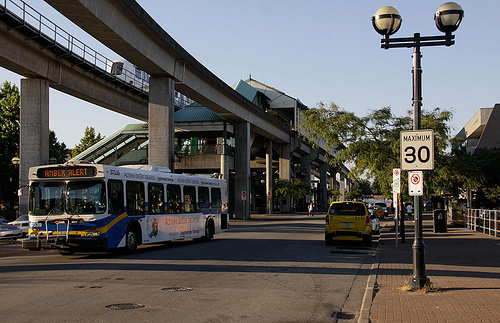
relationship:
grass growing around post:
[405, 277, 433, 297] [407, 28, 432, 293]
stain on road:
[208, 309, 230, 322] [1, 210, 372, 322]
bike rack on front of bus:
[44, 214, 70, 242] [30, 161, 231, 243]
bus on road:
[30, 161, 231, 243] [1, 210, 372, 322]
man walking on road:
[405, 200, 415, 221] [1, 210, 372, 322]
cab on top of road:
[325, 202, 373, 248] [1, 210, 372, 322]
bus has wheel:
[30, 161, 231, 243] [129, 227, 141, 252]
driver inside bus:
[78, 192, 98, 216] [30, 161, 231, 243]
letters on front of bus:
[39, 165, 89, 176] [30, 161, 231, 243]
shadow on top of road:
[261, 209, 327, 224] [1, 210, 372, 322]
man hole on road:
[165, 283, 191, 294] [1, 210, 372, 322]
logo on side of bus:
[149, 216, 161, 238] [30, 161, 231, 243]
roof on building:
[171, 102, 217, 124] [66, 79, 307, 214]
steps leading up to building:
[73, 126, 152, 165] [66, 79, 307, 214]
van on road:
[374, 197, 387, 216] [1, 210, 372, 322]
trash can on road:
[432, 209, 449, 236] [1, 210, 372, 322]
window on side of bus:
[110, 178, 122, 213] [30, 161, 231, 243]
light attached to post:
[374, 3, 461, 49] [407, 28, 432, 293]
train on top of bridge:
[111, 57, 163, 92] [1, 4, 160, 207]